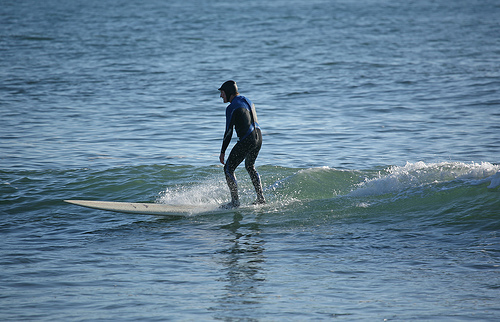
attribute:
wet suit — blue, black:
[212, 77, 273, 208]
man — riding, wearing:
[212, 74, 270, 209]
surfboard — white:
[56, 195, 275, 218]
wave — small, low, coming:
[243, 156, 499, 217]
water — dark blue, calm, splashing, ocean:
[3, 1, 499, 320]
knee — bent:
[221, 163, 233, 176]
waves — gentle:
[102, 155, 499, 229]